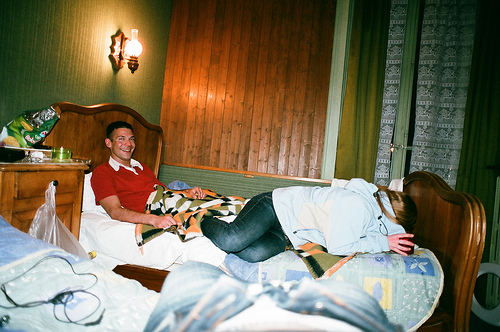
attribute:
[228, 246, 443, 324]
blanket — blue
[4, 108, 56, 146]
bag — crumpled, chips, open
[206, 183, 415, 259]
woman — hiding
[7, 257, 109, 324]
cord — black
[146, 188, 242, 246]
quilt — multicolored, green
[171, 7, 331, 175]
blinds — brown, wooden, wood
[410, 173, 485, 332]
footboard — oak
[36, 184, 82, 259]
bag — plastic, hanging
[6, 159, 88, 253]
nightstand — wooden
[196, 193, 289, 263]
jeans — blue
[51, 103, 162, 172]
headboard — wooden, brown, wood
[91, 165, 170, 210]
shirt — red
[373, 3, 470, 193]
drapes — sheer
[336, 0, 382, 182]
drape — green